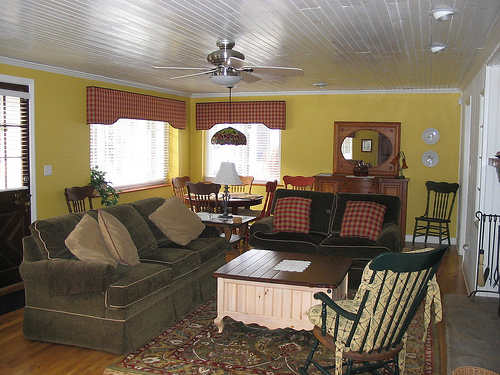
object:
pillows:
[96, 209, 141, 266]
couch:
[20, 196, 232, 353]